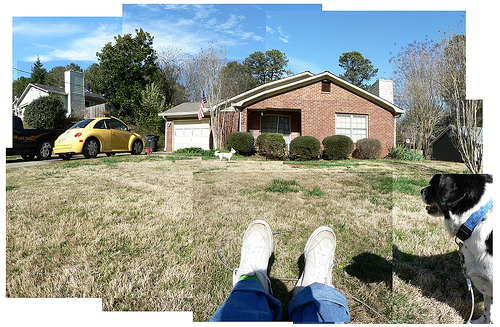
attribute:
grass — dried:
[133, 190, 226, 255]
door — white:
[169, 119, 215, 148]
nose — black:
[417, 182, 433, 198]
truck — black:
[0, 116, 63, 165]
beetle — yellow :
[53, 115, 145, 161]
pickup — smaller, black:
[11, 117, 63, 162]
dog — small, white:
[206, 146, 246, 163]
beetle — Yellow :
[35, 104, 161, 171]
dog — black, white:
[420, 172, 493, 323]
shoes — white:
[183, 183, 403, 300]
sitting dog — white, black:
[414, 173, 491, 320]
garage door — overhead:
[171, 117, 210, 152]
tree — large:
[89, 39, 176, 111]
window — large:
[326, 102, 373, 153]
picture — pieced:
[192, 171, 394, 324]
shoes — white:
[221, 198, 379, 290]